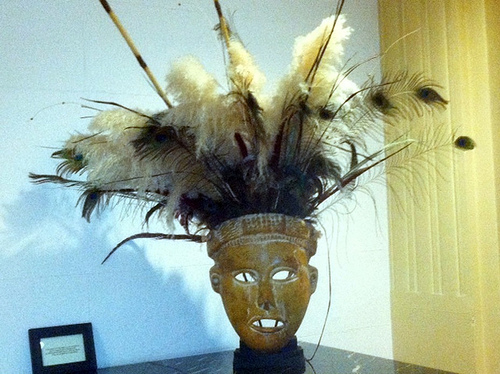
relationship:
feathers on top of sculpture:
[131, 121, 221, 195] [206, 213, 331, 352]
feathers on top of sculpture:
[310, 131, 482, 219] [206, 213, 331, 352]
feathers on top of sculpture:
[325, 72, 449, 161] [206, 213, 331, 352]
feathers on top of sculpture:
[225, 74, 272, 157] [206, 213, 331, 352]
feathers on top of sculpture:
[77, 186, 110, 219] [206, 213, 331, 352]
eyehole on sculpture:
[232, 267, 259, 285] [206, 213, 331, 352]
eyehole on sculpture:
[269, 269, 299, 281] [206, 213, 331, 352]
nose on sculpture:
[255, 294, 276, 310] [206, 213, 331, 352]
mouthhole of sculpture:
[251, 315, 285, 331] [206, 213, 331, 352]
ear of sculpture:
[210, 266, 224, 295] [206, 213, 331, 352]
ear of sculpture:
[309, 269, 318, 293] [206, 213, 331, 352]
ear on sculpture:
[210, 266, 224, 295] [206, 213, 331, 352]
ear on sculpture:
[309, 269, 318, 293] [206, 213, 331, 352]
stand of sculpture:
[231, 340, 304, 372] [206, 213, 331, 352]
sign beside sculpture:
[28, 323, 98, 373] [206, 213, 331, 352]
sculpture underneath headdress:
[206, 213, 331, 352] [27, 2, 475, 267]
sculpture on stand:
[206, 213, 331, 352] [231, 340, 304, 372]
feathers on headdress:
[225, 74, 272, 157] [27, 2, 475, 267]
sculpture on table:
[206, 213, 331, 352] [94, 351, 230, 374]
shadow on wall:
[2, 237, 223, 374] [2, 2, 161, 357]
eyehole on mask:
[269, 269, 299, 281] [206, 213, 331, 352]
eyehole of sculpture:
[232, 267, 259, 285] [206, 213, 331, 352]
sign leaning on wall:
[28, 323, 98, 373] [2, 2, 161, 357]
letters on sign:
[45, 347, 81, 357] [28, 323, 98, 373]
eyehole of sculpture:
[269, 269, 299, 281] [206, 213, 331, 352]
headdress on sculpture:
[27, 2, 475, 267] [206, 213, 331, 352]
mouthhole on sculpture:
[251, 315, 285, 331] [206, 213, 331, 352]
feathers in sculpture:
[225, 74, 272, 157] [206, 213, 331, 352]